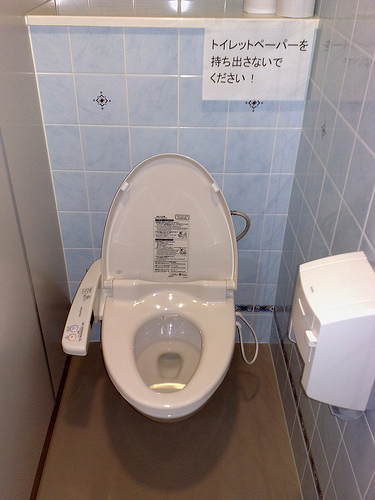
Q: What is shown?
A: A bathroom.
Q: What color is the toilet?
A: White.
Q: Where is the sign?
A: On the wall.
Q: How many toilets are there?
A: 1.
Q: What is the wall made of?
A: Tile.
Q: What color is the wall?
A: Blue.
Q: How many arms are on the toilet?
A: 1.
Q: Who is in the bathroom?
A: No one.